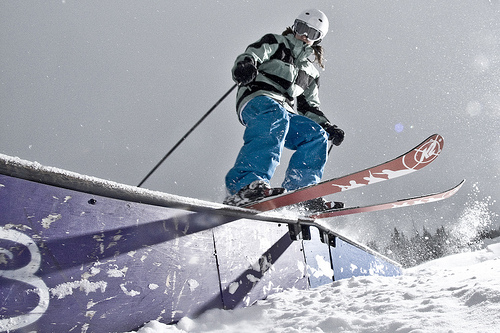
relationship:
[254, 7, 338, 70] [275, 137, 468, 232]
girl on skiboard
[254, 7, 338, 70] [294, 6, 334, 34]
girl wearing helmet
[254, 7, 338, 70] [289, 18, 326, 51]
girl wearing goggles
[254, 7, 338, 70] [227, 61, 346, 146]
girl wearing gloves